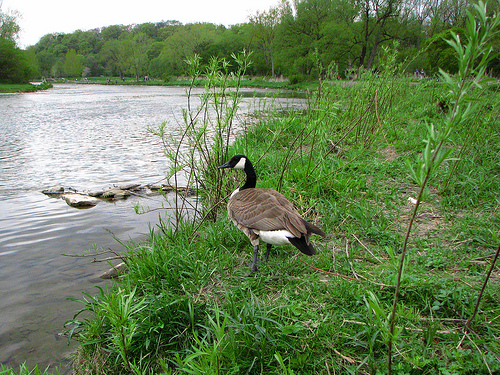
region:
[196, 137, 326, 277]
a goose walking in the green grass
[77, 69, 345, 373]
grass growing on the bank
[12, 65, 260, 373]
the sky reflected in the water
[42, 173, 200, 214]
stones breaking the surface of the water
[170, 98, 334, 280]
a goose on the bank of a stream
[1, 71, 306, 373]
the water in a stream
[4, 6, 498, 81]
green trees in the distance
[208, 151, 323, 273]
a white, brown, and black goose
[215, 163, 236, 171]
the black bill of a goose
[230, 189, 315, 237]
the brown feathers of a goose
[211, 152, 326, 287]
Goose standing in green grass.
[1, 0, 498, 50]
Gray sky behind tree line.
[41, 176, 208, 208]
Flat rocks in water.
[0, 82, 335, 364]
River flowing around a bend.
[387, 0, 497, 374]
Green plant growing in lower left corner.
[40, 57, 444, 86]
Cleared land on river bank.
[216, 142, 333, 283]
Bird with a black and white head.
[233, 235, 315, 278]
Black tail feathers and two black legs.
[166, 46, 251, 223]
Bird looking out behind clump of plants.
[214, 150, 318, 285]
A goose with white feathers under wing.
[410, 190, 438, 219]
White piece of trash.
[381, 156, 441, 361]
Long thin stick in grass.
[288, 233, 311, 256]
Black feathers on the duck.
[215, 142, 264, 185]
Black and white duck.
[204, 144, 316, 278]
Duck walking in the grass.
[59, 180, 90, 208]
Trail of rocks.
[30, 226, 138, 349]
Small pond of water.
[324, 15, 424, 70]
Big tree across river.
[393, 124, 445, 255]
Thin trail of dirt.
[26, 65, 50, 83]
White canoe across water.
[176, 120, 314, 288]
goose in the grass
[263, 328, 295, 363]
patch of green grass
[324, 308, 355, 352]
patch of green grass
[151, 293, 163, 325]
patch of green grass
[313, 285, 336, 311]
patch of green grass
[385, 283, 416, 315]
patch of green grass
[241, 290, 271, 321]
patch of green grass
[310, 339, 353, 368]
patch of green grass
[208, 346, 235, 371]
patch of green grass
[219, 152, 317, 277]
brown and black duck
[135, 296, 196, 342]
short brown and green grass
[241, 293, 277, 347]
short brown and green grass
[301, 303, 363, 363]
short brown and green grass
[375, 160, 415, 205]
short brown and green grass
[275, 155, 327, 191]
short brown and green grass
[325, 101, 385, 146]
short brown and green grass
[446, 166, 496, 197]
short brown and green grass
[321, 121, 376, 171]
short brown and green grass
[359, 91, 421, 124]
short brown and green grass